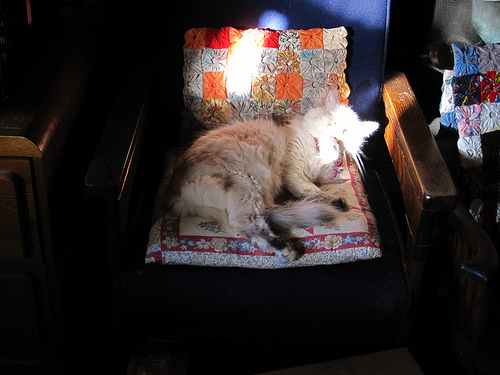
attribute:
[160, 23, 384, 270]
seat — multi colored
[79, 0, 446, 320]
seat — big, black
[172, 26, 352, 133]
seat cover — multi colored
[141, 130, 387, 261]
seat cover — multi colored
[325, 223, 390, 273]
seat cover — multi colored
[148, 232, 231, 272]
seat cover — multi colored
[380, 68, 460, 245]
seat handle — brown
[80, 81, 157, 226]
seat handle — brown